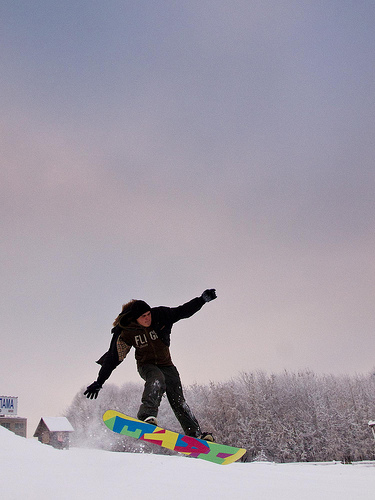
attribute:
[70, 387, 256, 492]
snowboard — multi colored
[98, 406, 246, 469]
snowboard — multicolored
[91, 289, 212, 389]
clothes — black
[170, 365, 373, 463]
trees — pine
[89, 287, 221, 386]
hoodie — black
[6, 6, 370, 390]
sky — partly cloudy